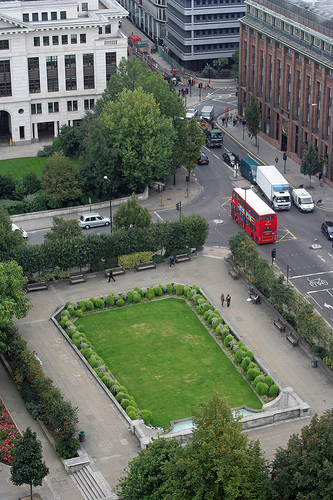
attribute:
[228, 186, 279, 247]
bus — red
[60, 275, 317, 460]
grass —  green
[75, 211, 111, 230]
car —  silver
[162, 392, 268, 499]
leaves —  green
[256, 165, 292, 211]
commercial truck —  white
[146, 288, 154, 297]
bush — green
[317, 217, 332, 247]
car —  black 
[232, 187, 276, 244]
bus — red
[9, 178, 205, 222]
sidewalk —  cemented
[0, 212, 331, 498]
park —  small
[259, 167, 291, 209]
truck —  white,  commercial 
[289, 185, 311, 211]
van —   white 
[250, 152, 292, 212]
truck —  white,  a semi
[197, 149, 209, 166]
car —  black 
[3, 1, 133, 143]
building —  large,  white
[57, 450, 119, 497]
steps — cement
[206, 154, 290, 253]
bus — double decker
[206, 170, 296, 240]
bus —   red ,  double decker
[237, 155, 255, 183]
truck —  commercial ,  blue